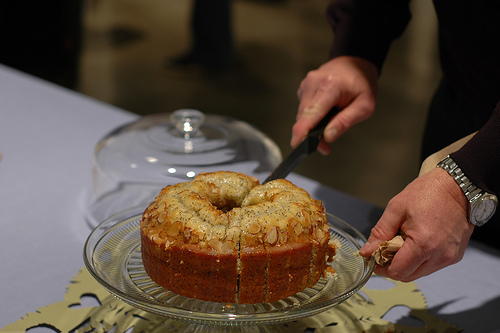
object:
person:
[288, 0, 500, 283]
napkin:
[366, 235, 406, 271]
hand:
[357, 169, 474, 285]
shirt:
[282, 0, 500, 190]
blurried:
[21, 5, 292, 66]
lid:
[82, 102, 282, 232]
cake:
[139, 169, 340, 303]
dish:
[80, 198, 377, 330]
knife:
[262, 112, 337, 183]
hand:
[289, 52, 382, 155]